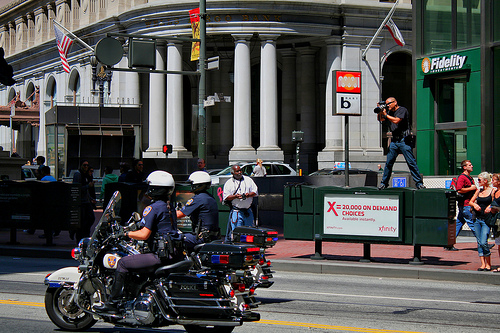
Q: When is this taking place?
A: Daytime.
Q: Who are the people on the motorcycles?
A: Police officers.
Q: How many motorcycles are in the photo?
A: Two.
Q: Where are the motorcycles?
A: Street.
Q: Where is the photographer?
A: Underneath the fidelity sign on the right.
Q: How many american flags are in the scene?
A: One.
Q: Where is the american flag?
A: On the side of the front of the white columns of the building on the left.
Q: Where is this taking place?
A: On the street.